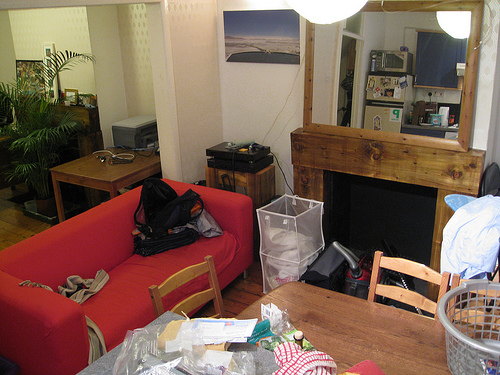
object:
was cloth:
[270, 341, 338, 375]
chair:
[366, 249, 451, 320]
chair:
[145, 253, 228, 320]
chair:
[446, 272, 500, 331]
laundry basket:
[436, 278, 500, 374]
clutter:
[110, 302, 339, 375]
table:
[224, 281, 500, 375]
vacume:
[332, 237, 424, 316]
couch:
[0, 176, 255, 375]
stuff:
[132, 227, 200, 258]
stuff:
[16, 267, 111, 365]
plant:
[0, 49, 95, 200]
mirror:
[302, 0, 486, 153]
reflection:
[312, 9, 472, 142]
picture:
[222, 9, 301, 66]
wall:
[0, 0, 499, 199]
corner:
[0, 6, 33, 26]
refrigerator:
[363, 72, 408, 135]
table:
[47, 145, 162, 223]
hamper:
[254, 192, 326, 296]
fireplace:
[289, 126, 488, 305]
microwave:
[370, 49, 414, 74]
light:
[282, 0, 372, 27]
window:
[411, 29, 470, 91]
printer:
[111, 115, 159, 149]